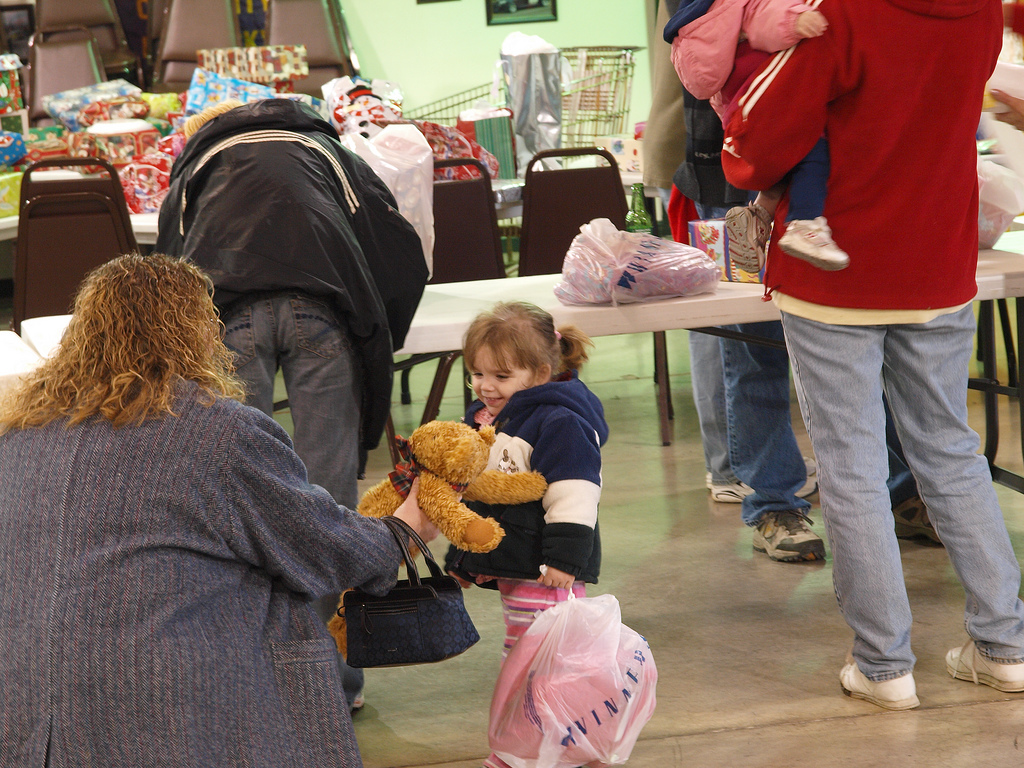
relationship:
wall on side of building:
[373, 52, 465, 166] [1, 5, 1021, 766]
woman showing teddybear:
[19, 257, 430, 767] [359, 419, 544, 549]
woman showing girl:
[19, 257, 430, 767] [441, 305, 658, 767]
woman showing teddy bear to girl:
[19, 257, 430, 767] [441, 305, 658, 767]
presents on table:
[8, 56, 505, 209] [3, 178, 533, 267]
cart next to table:
[490, 39, 642, 145] [2, 94, 473, 208]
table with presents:
[2, 94, 473, 208] [0, 40, 502, 216]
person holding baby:
[718, 1, 1014, 707] [659, 1, 847, 273]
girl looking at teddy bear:
[462, 301, 609, 763] [322, 418, 545, 661]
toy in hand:
[356, 421, 547, 554] [389, 472, 446, 553]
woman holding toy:
[0, 250, 459, 764] [356, 421, 547, 554]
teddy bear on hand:
[322, 418, 545, 661] [397, 478, 437, 561]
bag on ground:
[485, 580, 660, 766] [5, 295, 1021, 763]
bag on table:
[549, 215, 716, 308] [4, 246, 782, 462]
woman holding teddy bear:
[0, 250, 459, 764] [322, 418, 545, 661]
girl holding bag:
[446, 301, 609, 766] [482, 568, 657, 764]